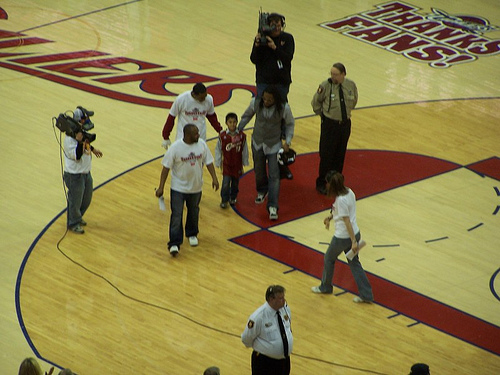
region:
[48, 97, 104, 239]
A cameraman filming the scene.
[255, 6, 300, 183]
A cameraman filming the scene.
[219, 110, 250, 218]
A young boy walking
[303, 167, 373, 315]
A wman walking across the court.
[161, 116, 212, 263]
A man walking down the court.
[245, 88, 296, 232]
A man walking with the boy.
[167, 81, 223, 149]
A man walking with the boy.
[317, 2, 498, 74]
Some writing on the court.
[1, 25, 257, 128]
The team logo on the court.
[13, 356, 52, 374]
The head of a woman watching the court.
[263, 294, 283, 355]
a security officer on the court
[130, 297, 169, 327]
part of a court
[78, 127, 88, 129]
part of a camera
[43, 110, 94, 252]
a camera man on the court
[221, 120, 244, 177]
a small boy in red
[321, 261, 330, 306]
left leg of a lady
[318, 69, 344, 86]
head of a man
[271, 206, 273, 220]
part of a white shoe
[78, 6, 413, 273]
people on a court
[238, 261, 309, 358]
security guard on the court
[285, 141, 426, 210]
red area of court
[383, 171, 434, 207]
free throw line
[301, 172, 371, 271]
woman in a white shirt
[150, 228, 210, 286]
white shoes on man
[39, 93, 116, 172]
camera in man's hand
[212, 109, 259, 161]
kid wearing a jersey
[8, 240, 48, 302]
three point line on court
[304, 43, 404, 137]
security guard with brown shirt on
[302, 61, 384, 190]
man standing in uniform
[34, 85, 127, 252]
man holding portable camera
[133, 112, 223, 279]
guy carrying white paper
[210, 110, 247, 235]
boy wearing red shirt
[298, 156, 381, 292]
lady carrying white paper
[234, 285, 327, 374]
man wearing headphone in uniform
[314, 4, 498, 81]
red letters with white frame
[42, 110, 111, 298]
cord on floor from camera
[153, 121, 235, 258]
man wearing white shoes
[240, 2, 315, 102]
guy looking through camera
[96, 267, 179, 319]
black line on court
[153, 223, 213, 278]
man wearing white sneakers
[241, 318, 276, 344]
black and gold emblem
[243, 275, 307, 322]
head phone on man's head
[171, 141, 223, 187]
symbol on white shirt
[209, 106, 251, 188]
boy standing on court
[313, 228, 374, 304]
woman wearing blue jeans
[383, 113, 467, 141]
yellow wood board on floot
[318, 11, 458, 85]
red and white words on floor